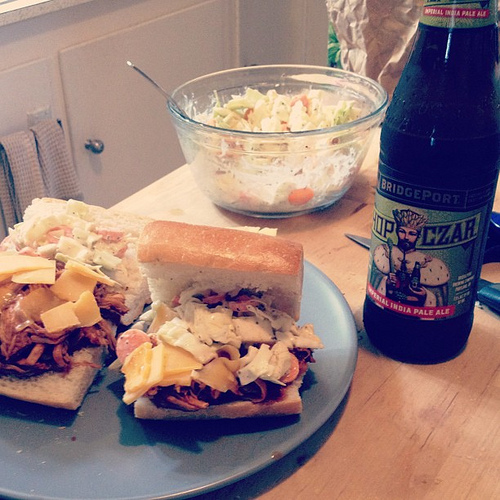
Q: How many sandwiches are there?
A: Two.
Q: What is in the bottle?
A: Beer.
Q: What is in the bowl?
A: Cole slaw.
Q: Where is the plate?
A: On the table.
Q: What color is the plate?
A: Blue.